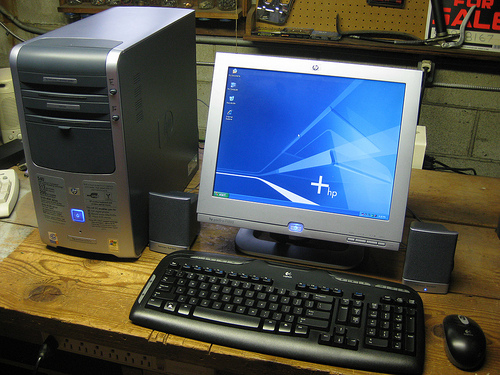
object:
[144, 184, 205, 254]
speaker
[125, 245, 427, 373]
keyboard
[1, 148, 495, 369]
desk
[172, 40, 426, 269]
computer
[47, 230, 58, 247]
sticker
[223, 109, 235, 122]
icon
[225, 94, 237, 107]
icon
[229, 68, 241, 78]
icon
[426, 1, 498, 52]
sign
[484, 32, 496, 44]
numbers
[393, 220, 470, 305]
speaker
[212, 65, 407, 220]
blue image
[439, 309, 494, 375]
mouse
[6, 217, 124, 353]
table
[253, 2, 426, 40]
pegboard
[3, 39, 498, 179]
wall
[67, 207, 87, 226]
logo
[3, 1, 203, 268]
tower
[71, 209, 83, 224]
light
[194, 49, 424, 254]
screen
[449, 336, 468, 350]
spot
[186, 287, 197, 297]
key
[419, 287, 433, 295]
blue light